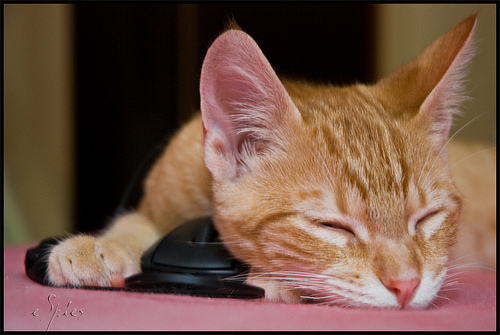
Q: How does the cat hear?
A: With it's ears.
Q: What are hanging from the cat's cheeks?
A: Whiskers.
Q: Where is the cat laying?
A: On the floor.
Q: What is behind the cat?
A: A doorway.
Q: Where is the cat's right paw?
A: Between two black objects.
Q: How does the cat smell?
A: With it's nose.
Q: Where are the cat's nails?
A: In it's paws.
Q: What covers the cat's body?
A: Fur.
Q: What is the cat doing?
A: Sleeping.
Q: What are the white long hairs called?
A: Whiskers.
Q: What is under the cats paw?
A: Black toy.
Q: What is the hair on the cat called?
A: Fur.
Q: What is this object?
A: Ear.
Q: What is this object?
A: Paw.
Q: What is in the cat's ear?
A: Fur.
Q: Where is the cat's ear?
A: On his head.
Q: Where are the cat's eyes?
A: On his face.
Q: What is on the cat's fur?
A: Stripes.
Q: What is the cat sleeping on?
A: A computer mouse.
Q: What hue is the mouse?
A: Black.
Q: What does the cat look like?
A: Orange cat with pink ears.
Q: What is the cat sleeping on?
A: Mouse.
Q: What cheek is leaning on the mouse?
A: Right cheek.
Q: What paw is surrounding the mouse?
A: Right paw.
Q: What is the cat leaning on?
A: A black mouse.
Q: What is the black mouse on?
A: A pink mouse pad.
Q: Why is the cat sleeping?
A: Its tired.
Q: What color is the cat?
A: Brown.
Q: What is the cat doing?
A: Sleeping.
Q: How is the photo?
A: Clear.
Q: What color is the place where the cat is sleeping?
A: Pink.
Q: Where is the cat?
A: In a house.